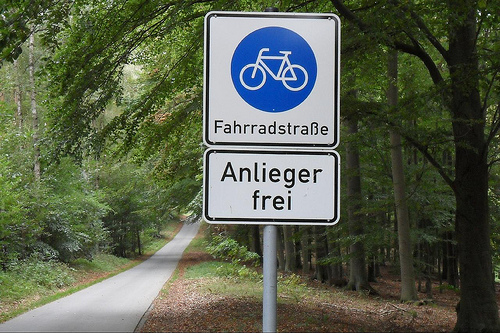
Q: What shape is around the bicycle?
A: Cirlce.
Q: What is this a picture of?
A: Bicycle path.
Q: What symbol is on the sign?
A: A symbol of a bike.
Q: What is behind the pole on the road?
A: Trees.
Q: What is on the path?
A: There is nothing.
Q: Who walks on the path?
A: There is noone.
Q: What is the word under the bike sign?
A: Fahrradstrabe.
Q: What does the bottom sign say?
A: Anlieger frei.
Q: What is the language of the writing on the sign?
A: German.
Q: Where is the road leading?
A: Into the woods.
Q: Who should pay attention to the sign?
A: Bicyclists.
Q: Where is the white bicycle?
A: In the blue circle.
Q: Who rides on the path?
A: Bicyclists.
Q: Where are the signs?
A: On the pole.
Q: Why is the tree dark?
A: In the shade.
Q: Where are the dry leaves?
A: On the ground.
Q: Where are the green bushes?
A: Beside the pathway.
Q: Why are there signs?
A: To advise bikes.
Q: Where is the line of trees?
A: Next to path.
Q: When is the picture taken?
A: Daytime.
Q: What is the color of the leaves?
A: Green.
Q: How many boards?
A: 2.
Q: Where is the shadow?
A: In the ground.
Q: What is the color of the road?
A: Grey.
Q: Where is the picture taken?
A: On the bicycle trail.